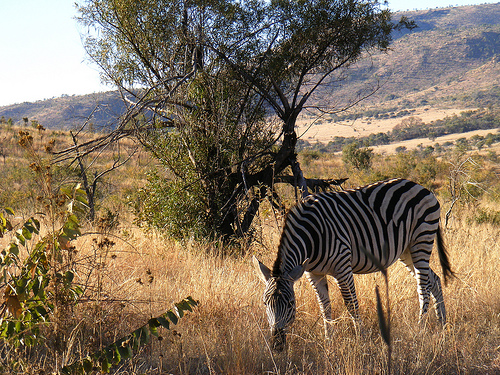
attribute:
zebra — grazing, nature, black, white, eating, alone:
[261, 185, 469, 325]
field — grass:
[18, 132, 497, 358]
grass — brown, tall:
[127, 235, 249, 333]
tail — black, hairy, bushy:
[433, 227, 462, 279]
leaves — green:
[56, 229, 75, 246]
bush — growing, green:
[5, 188, 156, 349]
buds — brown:
[374, 299, 395, 341]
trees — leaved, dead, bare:
[101, 7, 332, 207]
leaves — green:
[182, 44, 273, 129]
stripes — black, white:
[315, 221, 390, 255]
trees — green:
[326, 102, 405, 117]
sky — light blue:
[12, 2, 96, 86]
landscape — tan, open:
[19, 82, 484, 370]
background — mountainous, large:
[25, 39, 474, 138]